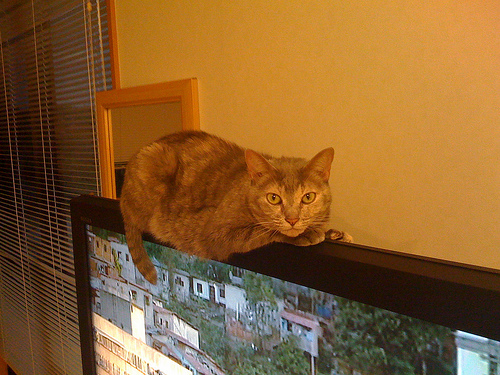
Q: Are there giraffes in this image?
A: No, there are no giraffes.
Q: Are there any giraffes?
A: No, there are no giraffes.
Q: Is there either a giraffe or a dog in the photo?
A: No, there are no giraffes or dogs.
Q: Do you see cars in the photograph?
A: No, there are no cars.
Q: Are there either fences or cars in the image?
A: No, there are no cars or fences.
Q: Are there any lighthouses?
A: No, there are no lighthouses.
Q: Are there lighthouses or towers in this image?
A: No, there are no lighthouses or towers.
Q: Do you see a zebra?
A: No, there are no zebras.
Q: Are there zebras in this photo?
A: No, there are no zebras.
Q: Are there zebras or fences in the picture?
A: No, there are no zebras or fences.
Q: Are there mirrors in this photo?
A: Yes, there is a mirror.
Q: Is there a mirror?
A: Yes, there is a mirror.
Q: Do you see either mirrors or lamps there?
A: Yes, there is a mirror.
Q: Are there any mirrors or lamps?
A: Yes, there is a mirror.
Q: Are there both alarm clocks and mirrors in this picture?
A: No, there is a mirror but no alarm clocks.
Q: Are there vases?
A: No, there are no vases.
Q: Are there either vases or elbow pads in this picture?
A: No, there are no vases or elbow pads.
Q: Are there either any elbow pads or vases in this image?
A: No, there are no vases or elbow pads.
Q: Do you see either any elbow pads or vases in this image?
A: No, there are no vases or elbow pads.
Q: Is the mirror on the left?
A: Yes, the mirror is on the left of the image.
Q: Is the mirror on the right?
A: No, the mirror is on the left of the image.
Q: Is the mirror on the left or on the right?
A: The mirror is on the left of the image.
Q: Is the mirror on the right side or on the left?
A: The mirror is on the left of the image.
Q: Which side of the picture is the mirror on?
A: The mirror is on the left of the image.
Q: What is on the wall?
A: The mirror is on the wall.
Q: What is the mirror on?
A: The mirror is on the wall.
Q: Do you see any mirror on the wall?
A: Yes, there is a mirror on the wall.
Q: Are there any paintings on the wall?
A: No, there is a mirror on the wall.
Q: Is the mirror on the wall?
A: Yes, the mirror is on the wall.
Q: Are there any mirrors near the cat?
A: Yes, there is a mirror near the cat.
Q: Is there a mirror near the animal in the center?
A: Yes, there is a mirror near the cat.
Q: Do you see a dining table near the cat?
A: No, there is a mirror near the cat.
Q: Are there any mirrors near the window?
A: Yes, there is a mirror near the window.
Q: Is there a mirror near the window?
A: Yes, there is a mirror near the window.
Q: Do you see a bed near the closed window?
A: No, there is a mirror near the window.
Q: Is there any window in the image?
A: Yes, there is a window.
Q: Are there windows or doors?
A: Yes, there is a window.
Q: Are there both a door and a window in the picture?
A: No, there is a window but no doors.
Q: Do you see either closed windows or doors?
A: Yes, there is a closed window.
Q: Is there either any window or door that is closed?
A: Yes, the window is closed.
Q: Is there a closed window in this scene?
A: Yes, there is a closed window.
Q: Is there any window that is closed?
A: Yes, there is a window that is closed.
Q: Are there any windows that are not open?
A: Yes, there is an closed window.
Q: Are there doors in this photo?
A: No, there are no doors.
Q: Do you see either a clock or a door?
A: No, there are no doors or clocks.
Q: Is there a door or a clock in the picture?
A: No, there are no doors or clocks.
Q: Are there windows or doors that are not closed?
A: No, there is a window but it is closed.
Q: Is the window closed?
A: Yes, the window is closed.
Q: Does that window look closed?
A: Yes, the window is closed.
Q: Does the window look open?
A: No, the window is closed.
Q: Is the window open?
A: No, the window is closed.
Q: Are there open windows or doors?
A: No, there is a window but it is closed.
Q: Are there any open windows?
A: No, there is a window but it is closed.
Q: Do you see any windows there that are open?
A: No, there is a window but it is closed.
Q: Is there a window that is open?
A: No, there is a window but it is closed.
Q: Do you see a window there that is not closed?
A: No, there is a window but it is closed.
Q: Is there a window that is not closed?
A: No, there is a window but it is closed.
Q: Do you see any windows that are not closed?
A: No, there is a window but it is closed.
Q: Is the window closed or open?
A: The window is closed.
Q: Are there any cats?
A: Yes, there is a cat.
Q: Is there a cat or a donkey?
A: Yes, there is a cat.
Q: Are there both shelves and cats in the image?
A: No, there is a cat but no shelves.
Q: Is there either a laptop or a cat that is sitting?
A: Yes, the cat is sitting.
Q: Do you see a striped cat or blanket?
A: Yes, there is a striped cat.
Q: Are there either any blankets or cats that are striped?
A: Yes, the cat is striped.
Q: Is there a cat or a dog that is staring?
A: Yes, the cat is staring.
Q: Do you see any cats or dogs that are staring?
A: Yes, the cat is staring.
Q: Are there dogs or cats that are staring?
A: Yes, the cat is staring.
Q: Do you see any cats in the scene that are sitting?
A: Yes, there is a cat that is sitting.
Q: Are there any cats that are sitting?
A: Yes, there is a cat that is sitting.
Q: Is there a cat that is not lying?
A: Yes, there is a cat that is sitting.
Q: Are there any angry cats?
A: Yes, there is an angry cat.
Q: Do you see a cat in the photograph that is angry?
A: Yes, there is a cat that is angry.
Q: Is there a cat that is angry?
A: Yes, there is a cat that is angry.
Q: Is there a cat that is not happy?
A: Yes, there is a angry cat.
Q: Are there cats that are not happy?
A: Yes, there is a angry cat.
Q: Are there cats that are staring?
A: Yes, there is a cat that is staring.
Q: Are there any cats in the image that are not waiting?
A: Yes, there is a cat that is staring.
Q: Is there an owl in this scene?
A: No, there are no owls.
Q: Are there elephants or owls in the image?
A: No, there are no owls or elephants.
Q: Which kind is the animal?
A: The animal is a cat.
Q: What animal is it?
A: The animal is a cat.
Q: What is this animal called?
A: This is a cat.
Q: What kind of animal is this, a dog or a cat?
A: This is a cat.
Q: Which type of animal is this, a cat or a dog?
A: This is a cat.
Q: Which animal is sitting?
A: The animal is a cat.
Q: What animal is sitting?
A: The animal is a cat.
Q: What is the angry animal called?
A: The animal is a cat.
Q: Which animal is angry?
A: The animal is a cat.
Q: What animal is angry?
A: The animal is a cat.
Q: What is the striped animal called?
A: The animal is a cat.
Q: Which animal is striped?
A: The animal is a cat.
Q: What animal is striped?
A: The animal is a cat.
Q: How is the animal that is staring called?
A: The animal is a cat.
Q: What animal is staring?
A: The animal is a cat.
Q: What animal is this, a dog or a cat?
A: This is a cat.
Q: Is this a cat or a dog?
A: This is a cat.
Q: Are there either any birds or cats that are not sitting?
A: No, there is a cat but it is sitting.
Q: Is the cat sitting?
A: Yes, the cat is sitting.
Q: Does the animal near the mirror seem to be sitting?
A: Yes, the cat is sitting.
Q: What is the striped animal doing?
A: The cat is sitting.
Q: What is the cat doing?
A: The cat is sitting.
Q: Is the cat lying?
A: No, the cat is sitting.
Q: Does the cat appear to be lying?
A: No, the cat is sitting.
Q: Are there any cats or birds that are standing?
A: No, there is a cat but it is sitting.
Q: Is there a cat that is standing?
A: No, there is a cat but it is sitting.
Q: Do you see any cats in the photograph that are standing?
A: No, there is a cat but it is sitting.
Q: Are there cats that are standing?
A: No, there is a cat but it is sitting.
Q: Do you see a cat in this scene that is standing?
A: No, there is a cat but it is sitting.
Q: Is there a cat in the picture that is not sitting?
A: No, there is a cat but it is sitting.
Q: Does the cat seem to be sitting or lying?
A: The cat is sitting.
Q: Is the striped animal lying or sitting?
A: The cat is sitting.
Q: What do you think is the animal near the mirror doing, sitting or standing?
A: The cat is sitting.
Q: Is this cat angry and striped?
A: Yes, the cat is angry and striped.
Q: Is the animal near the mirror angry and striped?
A: Yes, the cat is angry and striped.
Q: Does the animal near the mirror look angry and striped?
A: Yes, the cat is angry and striped.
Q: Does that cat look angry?
A: Yes, the cat is angry.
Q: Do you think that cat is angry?
A: Yes, the cat is angry.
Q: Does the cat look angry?
A: Yes, the cat is angry.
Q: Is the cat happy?
A: No, the cat is angry.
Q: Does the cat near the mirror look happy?
A: No, the cat is angry.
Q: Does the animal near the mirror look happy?
A: No, the cat is angry.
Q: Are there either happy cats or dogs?
A: No, there is a cat but it is angry.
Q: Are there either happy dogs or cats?
A: No, there is a cat but it is angry.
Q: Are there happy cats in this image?
A: No, there is a cat but it is angry.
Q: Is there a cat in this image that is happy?
A: No, there is a cat but it is angry.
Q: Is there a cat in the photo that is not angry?
A: No, there is a cat but it is angry.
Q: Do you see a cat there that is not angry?
A: No, there is a cat but it is angry.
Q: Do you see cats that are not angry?
A: No, there is a cat but it is angry.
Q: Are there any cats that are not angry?
A: No, there is a cat but it is angry.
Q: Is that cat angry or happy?
A: The cat is angry.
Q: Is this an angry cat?
A: Yes, this is an angry cat.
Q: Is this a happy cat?
A: No, this is an angry cat.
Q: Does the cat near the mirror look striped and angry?
A: Yes, the cat is striped and angry.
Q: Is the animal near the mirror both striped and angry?
A: Yes, the cat is striped and angry.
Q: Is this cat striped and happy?
A: No, the cat is striped but angry.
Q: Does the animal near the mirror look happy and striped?
A: No, the cat is striped but angry.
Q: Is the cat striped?
A: Yes, the cat is striped.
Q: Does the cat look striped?
A: Yes, the cat is striped.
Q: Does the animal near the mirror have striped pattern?
A: Yes, the cat is striped.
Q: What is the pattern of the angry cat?
A: The cat is striped.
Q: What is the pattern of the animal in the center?
A: The cat is striped.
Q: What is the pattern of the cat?
A: The cat is striped.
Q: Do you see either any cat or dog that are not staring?
A: No, there is a cat but it is staring.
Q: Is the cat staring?
A: Yes, the cat is staring.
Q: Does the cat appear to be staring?
A: Yes, the cat is staring.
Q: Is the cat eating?
A: No, the cat is staring.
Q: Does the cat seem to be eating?
A: No, the cat is staring.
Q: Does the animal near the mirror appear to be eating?
A: No, the cat is staring.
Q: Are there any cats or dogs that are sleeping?
A: No, there is a cat but it is staring.